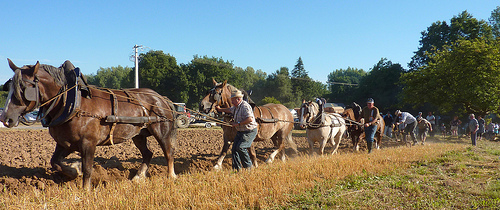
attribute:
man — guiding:
[204, 83, 275, 193]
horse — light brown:
[194, 75, 296, 169]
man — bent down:
[396, 108, 419, 145]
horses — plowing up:
[3, 55, 179, 194]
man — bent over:
[342, 87, 434, 167]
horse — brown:
[204, 83, 301, 161]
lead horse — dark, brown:
[8, 58, 185, 184]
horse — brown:
[43, 79, 249, 154]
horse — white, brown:
[297, 92, 345, 154]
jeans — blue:
[230, 129, 257, 170]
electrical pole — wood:
[129, 43, 146, 84]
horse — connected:
[0, 49, 400, 186]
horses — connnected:
[23, 85, 499, 185]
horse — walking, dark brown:
[2, 58, 184, 197]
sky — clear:
[1, 2, 499, 85]